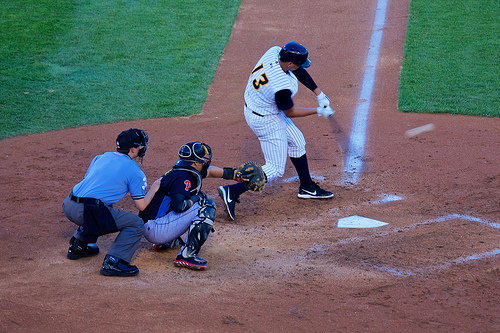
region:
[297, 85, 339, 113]
the glove is white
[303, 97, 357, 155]
the glove is white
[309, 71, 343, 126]
the glove is white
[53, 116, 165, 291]
crouched baseball umpire in blue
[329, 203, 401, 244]
homeplate on baseball diamond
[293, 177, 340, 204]
black shoe with Nike swish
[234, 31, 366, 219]
baseball player with batters safety helmet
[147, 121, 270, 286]
baseball catcher with mitt ready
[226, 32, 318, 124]
baseball player jersey with thirteen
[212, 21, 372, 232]
baseball player swinging bat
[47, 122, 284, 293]
umpire behind baseball catcher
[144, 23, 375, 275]
baseball umpire behind batter swinging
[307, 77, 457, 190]
baseball bat and ball in motion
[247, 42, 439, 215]
Batter swingin a tthe baseball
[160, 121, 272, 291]
Catcher waiting to catch the ball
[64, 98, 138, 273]
Umpire waiting to make a call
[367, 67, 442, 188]
The ball heading toward the catcher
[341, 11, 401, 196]
The third base line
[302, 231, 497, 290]
the left batters box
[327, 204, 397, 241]
The fields home plate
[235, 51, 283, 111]
Batter is wearin g number 13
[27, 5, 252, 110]
Foul territory on the field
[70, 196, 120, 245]
the umpires baseball bag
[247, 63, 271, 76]
The number 1 on the back of the batter's shirt.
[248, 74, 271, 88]
The number 3 on the back of the batter's shirt.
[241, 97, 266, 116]
The black belt the batter is wearing.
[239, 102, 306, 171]
The striped pants the batter is wearing.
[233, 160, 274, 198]
The glove in the catcher's hand.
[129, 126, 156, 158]
The face shield the umpire is wearing.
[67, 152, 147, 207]
The blue shirt the umpire is wearing.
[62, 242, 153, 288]
The black shoes the umpire is wearing.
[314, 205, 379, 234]
The base in front of the catcher.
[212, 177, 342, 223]
The Nike shoes the batter is wearing.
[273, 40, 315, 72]
Baseball helmet worn by batter.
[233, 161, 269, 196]
Mitt being worn by catcher.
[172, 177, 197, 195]
Red P on catcher's shoulder.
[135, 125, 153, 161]
Umpire's facemask.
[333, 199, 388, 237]
White home plate.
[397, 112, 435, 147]
Baseball in mid air.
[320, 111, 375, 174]
Baseball bat being swung.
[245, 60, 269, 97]
The number 13 on batter's back.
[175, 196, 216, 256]
Shin guard being worn by catcher.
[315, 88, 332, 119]
White gloves being worn by batter.